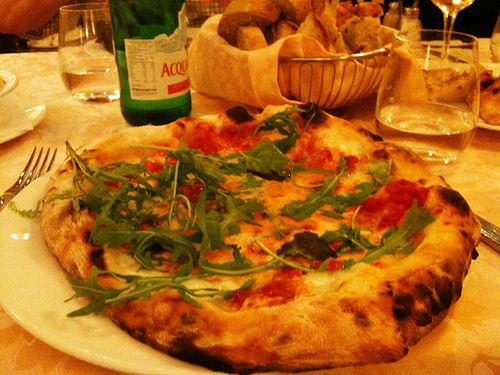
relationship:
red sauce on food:
[182, 119, 267, 151] [34, 103, 483, 375]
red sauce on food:
[363, 179, 429, 215] [34, 103, 483, 375]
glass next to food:
[370, 25, 482, 177] [34, 103, 483, 375]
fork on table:
[2, 142, 59, 203] [5, 4, 498, 371]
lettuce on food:
[234, 131, 298, 178] [34, 103, 483, 375]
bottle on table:
[105, 0, 190, 127] [1, 38, 499, 373]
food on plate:
[34, 103, 483, 375] [1, 160, 223, 372]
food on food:
[34, 103, 483, 375] [34, 103, 483, 375]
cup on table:
[369, 27, 484, 167] [1, 38, 499, 373]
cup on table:
[54, 2, 121, 103] [1, 38, 499, 373]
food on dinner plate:
[34, 103, 483, 375] [1, 115, 315, 375]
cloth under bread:
[186, 19, 321, 90] [259, 0, 382, 50]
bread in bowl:
[259, 0, 382, 50] [294, 66, 379, 96]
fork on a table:
[2, 142, 59, 203] [1, 38, 499, 373]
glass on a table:
[370, 29, 483, 177] [4, 30, 140, 185]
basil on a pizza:
[166, 206, 198, 234] [57, 84, 485, 365]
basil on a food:
[276, 165, 346, 227] [34, 103, 483, 375]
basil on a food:
[322, 157, 394, 223] [34, 103, 483, 375]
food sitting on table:
[49, 103, 470, 369] [5, 4, 498, 371]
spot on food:
[388, 253, 462, 338] [34, 103, 483, 375]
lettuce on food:
[93, 213, 195, 253] [34, 103, 483, 375]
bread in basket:
[218, 0, 387, 60] [192, 14, 409, 111]